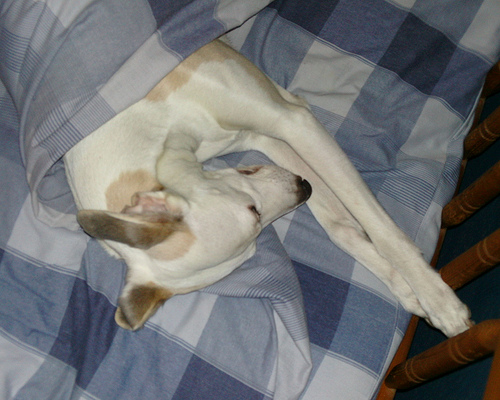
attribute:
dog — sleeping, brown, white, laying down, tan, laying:
[59, 35, 472, 340]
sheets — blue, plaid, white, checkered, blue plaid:
[1, 1, 495, 399]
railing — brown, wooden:
[461, 105, 499, 161]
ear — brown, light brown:
[68, 191, 186, 252]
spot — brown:
[99, 166, 163, 214]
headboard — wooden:
[371, 59, 496, 399]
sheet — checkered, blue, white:
[2, 3, 278, 234]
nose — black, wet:
[296, 173, 315, 203]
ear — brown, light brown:
[113, 277, 174, 335]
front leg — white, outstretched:
[240, 79, 473, 338]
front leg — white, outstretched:
[245, 135, 436, 329]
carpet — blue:
[397, 94, 498, 399]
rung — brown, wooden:
[441, 160, 499, 238]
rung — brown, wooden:
[428, 227, 499, 293]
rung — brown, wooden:
[384, 317, 498, 393]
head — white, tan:
[76, 160, 311, 335]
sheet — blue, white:
[211, 0, 499, 400]